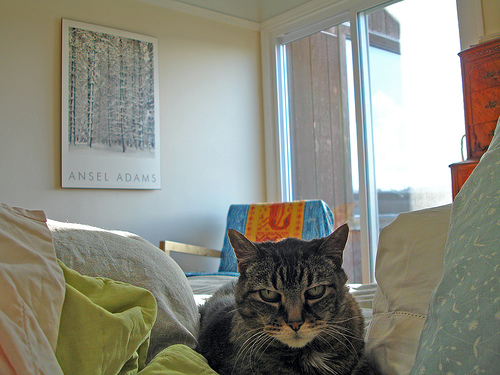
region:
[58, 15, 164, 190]
a picture on the wall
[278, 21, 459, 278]
a large window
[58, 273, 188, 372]
a green blanket next to the cat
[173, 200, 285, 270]
a chair behind the cat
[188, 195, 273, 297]
a blue and yellow chair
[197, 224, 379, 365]
a grey and white cat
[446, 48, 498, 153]
a dresser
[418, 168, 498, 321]
a blue blanket next to the cat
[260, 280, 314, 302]
the eyes of the cat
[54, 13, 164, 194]
Ansel Adams poster mounted on a wall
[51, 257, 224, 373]
Light green blanket on a bed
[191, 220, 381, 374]
A striped cat with green eyes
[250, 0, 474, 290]
A large window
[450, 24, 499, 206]
A tall chest of drawers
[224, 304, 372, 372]
White cat whiskers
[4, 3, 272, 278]
A beige colored wall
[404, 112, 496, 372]
Light blue fabric with white floral pattern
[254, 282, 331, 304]
Green cat eyes with dialated pupils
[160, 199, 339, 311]
Chair with bright colored covering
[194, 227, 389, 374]
cat on the bed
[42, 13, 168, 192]
image on the wall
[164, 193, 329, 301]
chair near the window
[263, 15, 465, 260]
window to the room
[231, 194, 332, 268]
covering on the chair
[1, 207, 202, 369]
covering on the bed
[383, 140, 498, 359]
covering on the bed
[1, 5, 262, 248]
wall image hangs on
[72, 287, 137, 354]
green material on bedding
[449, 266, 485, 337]
blue material on bedding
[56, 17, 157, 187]
Ansel Adams poster on wall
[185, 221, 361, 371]
gray and white cat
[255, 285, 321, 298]
green eyes of cat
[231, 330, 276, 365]
white whiskers of cat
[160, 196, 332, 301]
chair with wooden arms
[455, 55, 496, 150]
wooden drawers with metal handles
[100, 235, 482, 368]
cat laying on the bed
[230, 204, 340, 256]
blue, orange and red fabric on chair back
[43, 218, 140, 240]
sunlight shining on blanket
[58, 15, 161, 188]
ansel adams print on the wall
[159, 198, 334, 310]
chair with a blue and orange fabric on it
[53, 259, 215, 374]
bright yellow blanket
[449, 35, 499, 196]
orange colored hutch